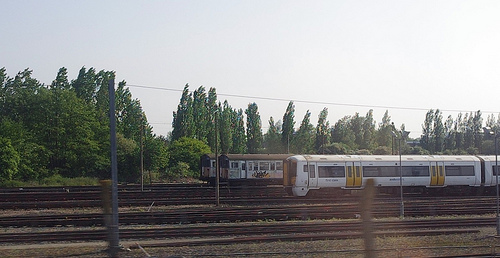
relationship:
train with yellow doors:
[285, 152, 497, 193] [341, 157, 363, 189]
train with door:
[285, 152, 497, 193] [425, 155, 446, 189]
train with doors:
[285, 152, 497, 193] [340, 164, 365, 194]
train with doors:
[278, 152, 498, 201] [341, 162, 453, 186]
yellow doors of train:
[428, 159, 447, 189] [284, 153, 499, 195]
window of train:
[315, 159, 348, 184] [275, 147, 498, 203]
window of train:
[355, 162, 432, 179] [284, 146, 498, 196]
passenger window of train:
[443, 164, 465, 176] [284, 153, 499, 195]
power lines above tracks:
[21, 72, 486, 128] [16, 181, 498, 248]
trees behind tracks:
[0, 64, 499, 184] [0, 185, 499, 257]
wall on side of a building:
[220, 152, 297, 179] [197, 147, 293, 180]